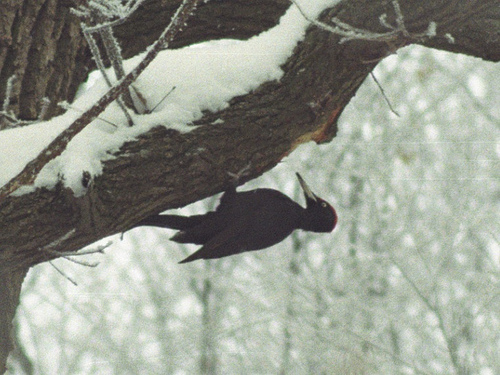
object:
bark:
[0, 0, 20, 69]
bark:
[20, 0, 60, 118]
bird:
[120, 159, 337, 264]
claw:
[227, 159, 253, 180]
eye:
[321, 202, 327, 208]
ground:
[15, 42, 500, 375]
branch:
[74, 21, 135, 128]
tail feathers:
[121, 208, 189, 240]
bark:
[106, 137, 197, 170]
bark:
[402, 0, 500, 63]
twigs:
[148, 85, 178, 117]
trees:
[171, 195, 254, 375]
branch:
[293, 0, 402, 41]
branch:
[403, 21, 438, 40]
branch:
[367, 69, 402, 119]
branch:
[37, 227, 77, 249]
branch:
[54, 100, 119, 129]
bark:
[235, 96, 312, 138]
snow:
[15, 44, 500, 375]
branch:
[93, 0, 137, 112]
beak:
[294, 171, 318, 202]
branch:
[60, 255, 98, 268]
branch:
[46, 240, 114, 263]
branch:
[41, 252, 78, 287]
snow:
[0, 0, 340, 198]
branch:
[0, 0, 200, 199]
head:
[293, 171, 338, 234]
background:
[16, 43, 499, 375]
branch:
[0, 72, 21, 130]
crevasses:
[197, 151, 215, 166]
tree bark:
[0, 189, 84, 245]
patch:
[327, 205, 338, 231]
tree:
[0, 0, 497, 375]